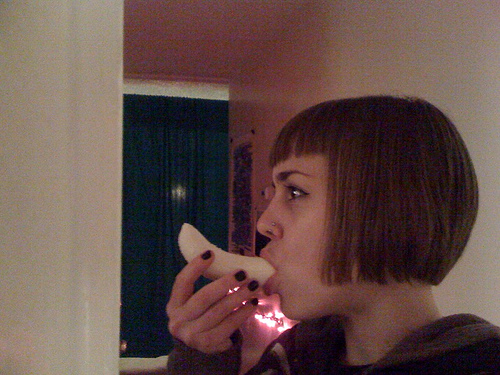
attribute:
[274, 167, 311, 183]
eyebrow — brown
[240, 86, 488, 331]
hair — red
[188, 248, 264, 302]
nail polish — brown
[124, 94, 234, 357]
curtain — blue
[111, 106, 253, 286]
curtain — green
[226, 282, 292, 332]
light — pink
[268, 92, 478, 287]
bobcut — short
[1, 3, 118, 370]
wall — white